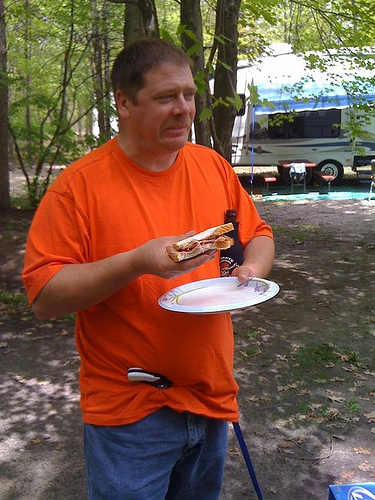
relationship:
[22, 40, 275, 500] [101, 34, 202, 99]
man has brown hair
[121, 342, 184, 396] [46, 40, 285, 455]
white item around man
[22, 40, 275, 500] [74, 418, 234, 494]
man wears blue jeans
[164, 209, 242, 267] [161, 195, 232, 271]
holding sandwich holding sandwich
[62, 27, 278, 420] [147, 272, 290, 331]
man holds white plate